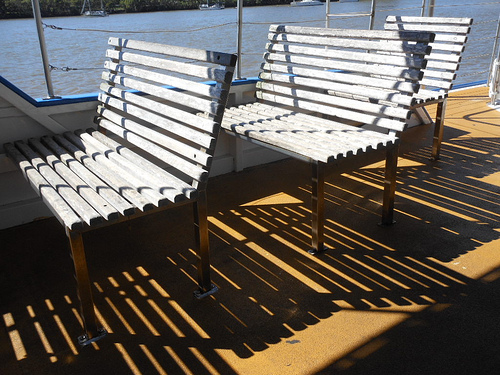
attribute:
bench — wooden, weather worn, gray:
[3, 36, 237, 343]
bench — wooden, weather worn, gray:
[191, 24, 435, 256]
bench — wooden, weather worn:
[323, 14, 473, 161]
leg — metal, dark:
[64, 226, 106, 343]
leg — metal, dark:
[192, 189, 217, 296]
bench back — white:
[93, 36, 238, 190]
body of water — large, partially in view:
[0, 0, 499, 99]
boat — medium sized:
[0, 0, 499, 375]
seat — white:
[3, 127, 198, 231]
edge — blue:
[0, 69, 487, 108]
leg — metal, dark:
[308, 159, 329, 255]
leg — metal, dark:
[377, 146, 399, 229]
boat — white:
[290, 0, 325, 7]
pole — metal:
[234, 1, 247, 82]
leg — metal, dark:
[427, 98, 447, 162]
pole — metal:
[323, 0, 330, 70]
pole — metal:
[486, 16, 499, 84]